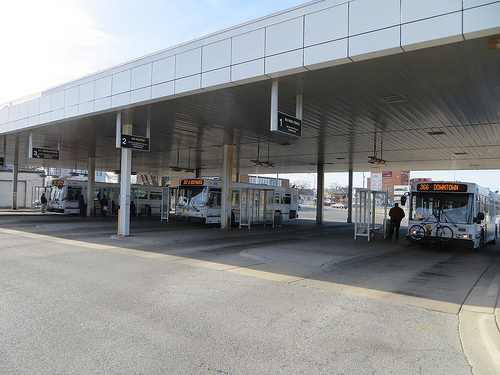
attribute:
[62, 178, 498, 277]
buses — parked, in terminal, at stop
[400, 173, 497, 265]
bus — large, white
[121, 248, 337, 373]
road — concrete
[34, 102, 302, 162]
signs — black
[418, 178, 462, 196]
sign — lit, orange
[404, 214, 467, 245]
bike — rack-mounted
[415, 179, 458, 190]
lettering — yellow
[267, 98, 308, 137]
sign — black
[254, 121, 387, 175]
lights — hanging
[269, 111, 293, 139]
number — 1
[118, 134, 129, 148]
number — 2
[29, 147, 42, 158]
number — 3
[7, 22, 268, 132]
tiles — white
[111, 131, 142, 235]
pillar — white